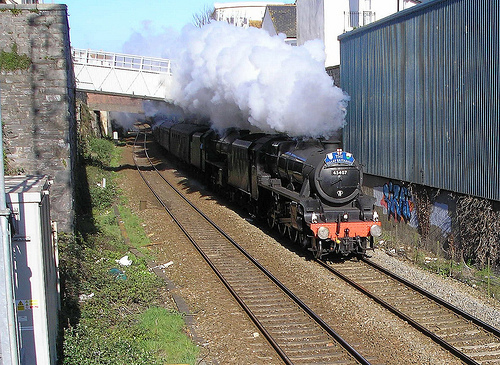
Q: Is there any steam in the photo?
A: Yes, there is steam.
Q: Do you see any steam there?
A: Yes, there is steam.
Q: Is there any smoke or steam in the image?
A: Yes, there is steam.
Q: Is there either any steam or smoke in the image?
A: Yes, there is steam.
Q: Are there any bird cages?
A: No, there are no bird cages.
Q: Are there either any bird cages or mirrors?
A: No, there are no bird cages or mirrors.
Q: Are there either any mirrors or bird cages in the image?
A: No, there are no bird cages or mirrors.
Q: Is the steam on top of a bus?
A: No, the steam is on top of the train.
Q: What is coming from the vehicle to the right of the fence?
A: The steam is coming from the train.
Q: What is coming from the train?
A: The steam is coming from the train.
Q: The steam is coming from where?
A: The steam is coming from the train.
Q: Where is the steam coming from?
A: The steam is coming from the train.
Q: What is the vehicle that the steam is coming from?
A: The vehicle is a train.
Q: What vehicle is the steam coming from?
A: The steam is coming from the train.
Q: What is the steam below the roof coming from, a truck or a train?
A: The steam is coming from a train.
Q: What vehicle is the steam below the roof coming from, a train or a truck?
A: The steam is coming from a train.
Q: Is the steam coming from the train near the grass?
A: Yes, the steam is coming from the train.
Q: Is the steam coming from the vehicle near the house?
A: Yes, the steam is coming from the train.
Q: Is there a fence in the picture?
A: Yes, there is a fence.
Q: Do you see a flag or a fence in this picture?
A: Yes, there is a fence.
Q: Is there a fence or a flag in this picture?
A: Yes, there is a fence.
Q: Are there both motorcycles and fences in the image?
A: No, there is a fence but no motorcycles.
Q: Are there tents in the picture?
A: No, there are no tents.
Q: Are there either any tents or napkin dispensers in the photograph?
A: No, there are no tents or napkin dispensers.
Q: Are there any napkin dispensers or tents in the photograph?
A: No, there are no tents or napkin dispensers.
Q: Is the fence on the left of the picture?
A: Yes, the fence is on the left of the image.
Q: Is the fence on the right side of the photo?
A: No, the fence is on the left of the image.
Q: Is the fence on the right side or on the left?
A: The fence is on the left of the image.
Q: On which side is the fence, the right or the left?
A: The fence is on the left of the image.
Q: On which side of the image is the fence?
A: The fence is on the left of the image.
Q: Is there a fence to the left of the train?
A: Yes, there is a fence to the left of the train.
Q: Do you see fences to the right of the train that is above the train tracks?
A: No, the fence is to the left of the train.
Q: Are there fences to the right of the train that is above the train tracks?
A: No, the fence is to the left of the train.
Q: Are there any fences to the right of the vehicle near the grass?
A: No, the fence is to the left of the train.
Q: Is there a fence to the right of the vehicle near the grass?
A: No, the fence is to the left of the train.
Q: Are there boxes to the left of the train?
A: No, there is a fence to the left of the train.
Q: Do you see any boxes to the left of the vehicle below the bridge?
A: No, there is a fence to the left of the train.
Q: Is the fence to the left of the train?
A: Yes, the fence is to the left of the train.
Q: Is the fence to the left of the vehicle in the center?
A: Yes, the fence is to the left of the train.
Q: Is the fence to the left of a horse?
A: No, the fence is to the left of the train.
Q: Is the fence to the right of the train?
A: No, the fence is to the left of the train.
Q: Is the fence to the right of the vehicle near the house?
A: No, the fence is to the left of the train.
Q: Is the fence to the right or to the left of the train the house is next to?
A: The fence is to the left of the train.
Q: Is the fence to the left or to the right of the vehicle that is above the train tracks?
A: The fence is to the left of the train.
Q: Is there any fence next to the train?
A: Yes, there is a fence next to the train.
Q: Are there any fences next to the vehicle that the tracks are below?
A: Yes, there is a fence next to the train.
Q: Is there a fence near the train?
A: Yes, there is a fence near the train.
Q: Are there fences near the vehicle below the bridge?
A: Yes, there is a fence near the train.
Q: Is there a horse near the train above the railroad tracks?
A: No, there is a fence near the train.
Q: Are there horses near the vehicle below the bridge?
A: No, there is a fence near the train.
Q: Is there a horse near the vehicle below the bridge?
A: No, there is a fence near the train.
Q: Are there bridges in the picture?
A: Yes, there is a bridge.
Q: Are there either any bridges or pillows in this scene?
A: Yes, there is a bridge.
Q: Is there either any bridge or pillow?
A: Yes, there is a bridge.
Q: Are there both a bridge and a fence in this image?
A: Yes, there are both a bridge and a fence.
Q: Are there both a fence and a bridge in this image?
A: Yes, there are both a bridge and a fence.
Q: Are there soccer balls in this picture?
A: No, there are no soccer balls.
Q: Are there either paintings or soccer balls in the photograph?
A: No, there are no soccer balls or paintings.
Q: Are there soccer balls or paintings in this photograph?
A: No, there are no soccer balls or paintings.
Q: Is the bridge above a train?
A: Yes, the bridge is above a train.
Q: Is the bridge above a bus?
A: No, the bridge is above a train.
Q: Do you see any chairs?
A: No, there are no chairs.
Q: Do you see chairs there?
A: No, there are no chairs.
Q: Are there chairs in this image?
A: No, there are no chairs.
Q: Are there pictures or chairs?
A: No, there are no chairs or pictures.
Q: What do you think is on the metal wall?
A: The graffiti is on the wall.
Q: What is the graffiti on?
A: The graffiti is on the wall.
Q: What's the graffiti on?
A: The graffiti is on the wall.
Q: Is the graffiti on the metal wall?
A: Yes, the graffiti is on the wall.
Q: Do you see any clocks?
A: No, there are no clocks.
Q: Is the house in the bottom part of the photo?
A: No, the house is in the top of the image.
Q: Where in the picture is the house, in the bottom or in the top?
A: The house is in the top of the image.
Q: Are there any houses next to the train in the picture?
A: Yes, there is a house next to the train.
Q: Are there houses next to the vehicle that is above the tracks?
A: Yes, there is a house next to the train.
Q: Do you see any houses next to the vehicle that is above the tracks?
A: Yes, there is a house next to the train.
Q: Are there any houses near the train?
A: Yes, there is a house near the train.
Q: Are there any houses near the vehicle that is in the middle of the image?
A: Yes, there is a house near the train.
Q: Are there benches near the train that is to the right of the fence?
A: No, there is a house near the train.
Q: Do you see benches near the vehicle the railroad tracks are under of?
A: No, there is a house near the train.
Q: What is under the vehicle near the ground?
A: The train tracks are under the train.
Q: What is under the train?
A: The train tracks are under the train.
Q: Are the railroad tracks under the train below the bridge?
A: Yes, the railroad tracks are under the train.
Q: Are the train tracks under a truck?
A: No, the train tracks are under the train.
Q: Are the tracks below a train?
A: Yes, the tracks are below a train.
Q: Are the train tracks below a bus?
A: No, the train tracks are below a train.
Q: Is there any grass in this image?
A: Yes, there is grass.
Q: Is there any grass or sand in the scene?
A: Yes, there is grass.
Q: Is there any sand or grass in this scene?
A: Yes, there is grass.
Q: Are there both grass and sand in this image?
A: No, there is grass but no sand.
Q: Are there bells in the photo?
A: No, there are no bells.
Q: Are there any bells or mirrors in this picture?
A: No, there are no bells or mirrors.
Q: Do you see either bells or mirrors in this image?
A: No, there are no bells or mirrors.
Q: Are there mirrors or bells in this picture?
A: No, there are no bells or mirrors.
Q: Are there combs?
A: No, there are no combs.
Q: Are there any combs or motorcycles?
A: No, there are no combs or motorcycles.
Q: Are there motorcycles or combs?
A: No, there are no combs or motorcycles.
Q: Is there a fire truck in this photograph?
A: No, there are no fire trucks.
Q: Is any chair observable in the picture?
A: No, there are no chairs.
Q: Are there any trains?
A: Yes, there is a train.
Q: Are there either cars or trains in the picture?
A: Yes, there is a train.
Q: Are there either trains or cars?
A: Yes, there is a train.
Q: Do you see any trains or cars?
A: Yes, there is a train.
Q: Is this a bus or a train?
A: This is a train.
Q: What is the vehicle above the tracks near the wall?
A: The vehicle is a train.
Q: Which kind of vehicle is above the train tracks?
A: The vehicle is a train.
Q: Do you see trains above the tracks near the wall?
A: Yes, there is a train above the train tracks.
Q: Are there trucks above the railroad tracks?
A: No, there is a train above the railroad tracks.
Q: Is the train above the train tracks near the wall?
A: Yes, the train is above the tracks.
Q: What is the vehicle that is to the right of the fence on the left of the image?
A: The vehicle is a train.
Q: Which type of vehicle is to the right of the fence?
A: The vehicle is a train.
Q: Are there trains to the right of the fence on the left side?
A: Yes, there is a train to the right of the fence.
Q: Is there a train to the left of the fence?
A: No, the train is to the right of the fence.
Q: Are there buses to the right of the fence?
A: No, there is a train to the right of the fence.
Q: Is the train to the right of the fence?
A: Yes, the train is to the right of the fence.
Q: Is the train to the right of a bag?
A: No, the train is to the right of the fence.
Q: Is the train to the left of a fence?
A: No, the train is to the right of a fence.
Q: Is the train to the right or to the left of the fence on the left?
A: The train is to the right of the fence.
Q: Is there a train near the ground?
A: Yes, there is a train near the ground.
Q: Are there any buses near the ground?
A: No, there is a train near the ground.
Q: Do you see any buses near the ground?
A: No, there is a train near the ground.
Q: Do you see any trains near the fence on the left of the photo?
A: Yes, there is a train near the fence.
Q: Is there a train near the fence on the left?
A: Yes, there is a train near the fence.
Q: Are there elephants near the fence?
A: No, there is a train near the fence.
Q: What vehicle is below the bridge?
A: The vehicle is a train.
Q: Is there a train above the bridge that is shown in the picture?
A: No, the train is below the bridge.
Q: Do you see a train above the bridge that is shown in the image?
A: No, the train is below the bridge.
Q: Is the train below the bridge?
A: Yes, the train is below the bridge.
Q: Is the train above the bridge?
A: No, the train is below the bridge.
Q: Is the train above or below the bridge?
A: The train is below the bridge.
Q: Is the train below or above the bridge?
A: The train is below the bridge.